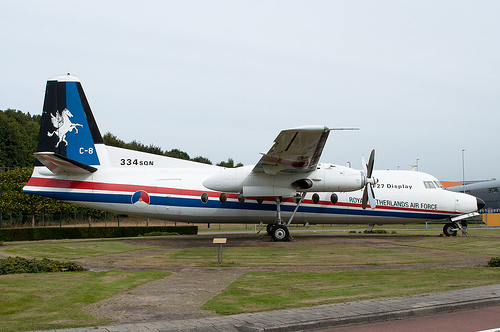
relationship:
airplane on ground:
[23, 70, 487, 237] [0, 223, 499, 330]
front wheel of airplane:
[440, 223, 461, 238] [23, 70, 487, 237]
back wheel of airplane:
[267, 224, 289, 243] [23, 70, 487, 237]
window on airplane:
[198, 193, 210, 204] [23, 70, 487, 237]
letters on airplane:
[407, 201, 438, 211] [23, 70, 487, 237]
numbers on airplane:
[120, 157, 139, 167] [23, 70, 487, 237]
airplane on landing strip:
[23, 70, 487, 237] [130, 234, 499, 245]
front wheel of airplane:
[440, 220, 465, 240] [23, 70, 487, 237]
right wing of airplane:
[238, 127, 362, 177] [23, 70, 487, 237]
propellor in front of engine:
[358, 148, 380, 215] [204, 163, 364, 202]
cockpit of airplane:
[420, 178, 441, 192] [23, 70, 487, 237]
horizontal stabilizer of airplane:
[30, 150, 96, 178] [23, 70, 487, 237]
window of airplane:
[198, 190, 211, 208] [23, 70, 487, 237]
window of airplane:
[215, 188, 229, 207] [23, 70, 487, 237]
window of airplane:
[234, 192, 248, 209] [23, 70, 487, 237]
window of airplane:
[327, 191, 340, 210] [23, 70, 487, 237]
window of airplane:
[307, 190, 321, 209] [23, 70, 487, 237]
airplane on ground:
[27, 117, 444, 232] [57, 223, 386, 311]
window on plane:
[198, 193, 210, 204] [101, 147, 350, 217]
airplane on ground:
[23, 70, 487, 237] [28, 229, 458, 315]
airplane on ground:
[23, 70, 487, 237] [9, 229, 483, 316]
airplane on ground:
[23, 70, 487, 237] [22, 230, 479, 328]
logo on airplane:
[44, 107, 84, 154] [23, 70, 487, 237]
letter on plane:
[386, 182, 392, 188] [20, 62, 497, 289]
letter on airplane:
[386, 182, 392, 188] [23, 70, 487, 237]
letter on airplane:
[399, 177, 406, 190] [23, 70, 487, 237]